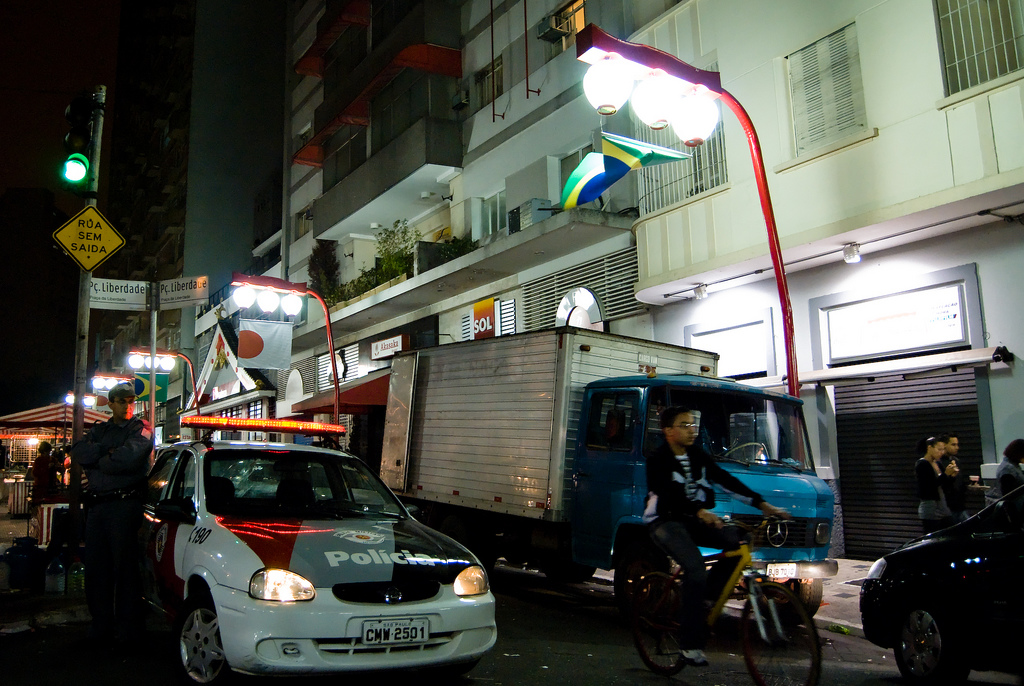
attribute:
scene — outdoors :
[370, 544, 424, 565]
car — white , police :
[115, 397, 504, 654]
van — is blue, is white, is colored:
[378, 317, 819, 589]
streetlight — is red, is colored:
[569, 21, 846, 614]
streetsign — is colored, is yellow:
[55, 189, 133, 279]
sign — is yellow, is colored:
[454, 289, 497, 346]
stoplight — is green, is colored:
[36, 138, 91, 189]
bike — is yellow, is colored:
[615, 501, 854, 679]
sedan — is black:
[822, 400, 1022, 667]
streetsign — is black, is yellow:
[54, 200, 116, 276]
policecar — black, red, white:
[130, 437, 497, 684]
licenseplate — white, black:
[359, 608, 432, 644]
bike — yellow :
[604, 533, 834, 681]